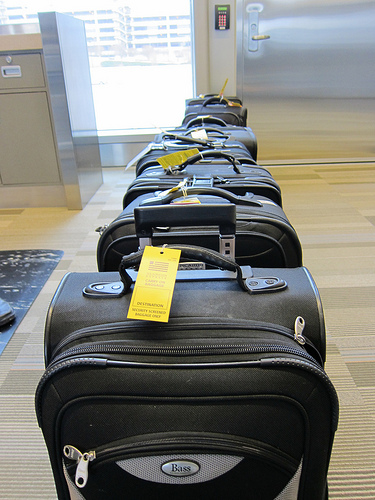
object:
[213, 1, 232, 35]
keypad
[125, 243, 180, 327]
tag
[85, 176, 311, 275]
suitcase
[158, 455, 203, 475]
bass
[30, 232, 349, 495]
suitcases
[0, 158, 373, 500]
floor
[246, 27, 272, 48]
handle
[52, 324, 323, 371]
zipper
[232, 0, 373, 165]
door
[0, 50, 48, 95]
drawer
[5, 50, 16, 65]
lock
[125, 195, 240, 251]
handle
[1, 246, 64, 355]
rug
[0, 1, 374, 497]
airport